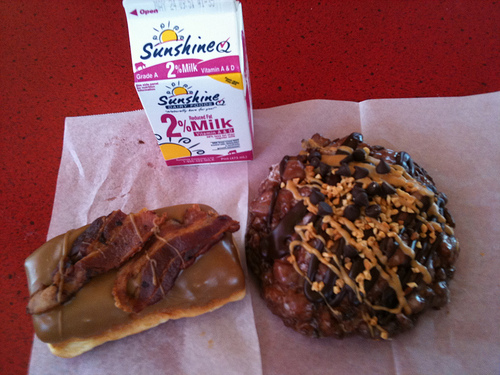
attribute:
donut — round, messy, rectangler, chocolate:
[254, 139, 461, 337]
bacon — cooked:
[87, 214, 227, 300]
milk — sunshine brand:
[121, 4, 264, 164]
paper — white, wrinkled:
[299, 99, 421, 122]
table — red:
[309, 35, 393, 71]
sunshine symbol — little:
[154, 20, 185, 44]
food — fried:
[7, 204, 275, 365]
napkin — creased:
[86, 120, 117, 179]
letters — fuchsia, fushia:
[160, 95, 221, 106]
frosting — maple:
[322, 149, 345, 165]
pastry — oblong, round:
[287, 113, 407, 221]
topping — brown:
[310, 175, 361, 211]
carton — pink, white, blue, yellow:
[145, 63, 237, 79]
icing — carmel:
[394, 155, 423, 178]